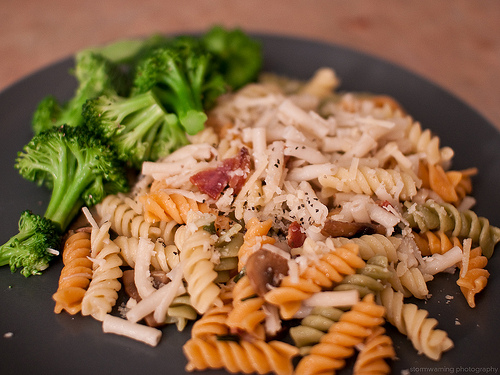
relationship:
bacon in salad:
[321, 219, 370, 234] [117, 57, 407, 282]